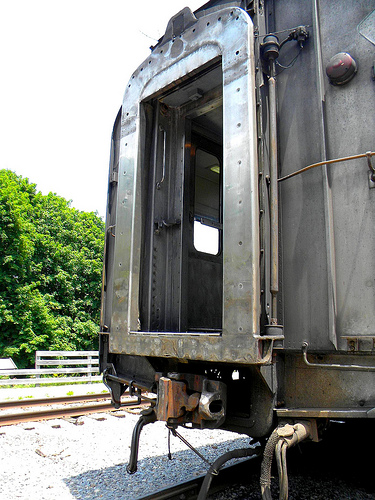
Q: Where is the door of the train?
A: In the back.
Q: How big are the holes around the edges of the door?
A: They are small.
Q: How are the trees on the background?
A: Thick and green.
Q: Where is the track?
A: On the ground.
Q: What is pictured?
A: Train.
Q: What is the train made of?
A: Metal.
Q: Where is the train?
A: On train tracks.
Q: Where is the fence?
A: On the other side of the tracks.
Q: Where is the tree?
A: Behind the fence.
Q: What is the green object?
A: Tree.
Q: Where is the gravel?
A: By the train tracks.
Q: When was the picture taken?
A: During day hours.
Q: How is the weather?
A: Sunny.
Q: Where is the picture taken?
A: At the rear of the train.